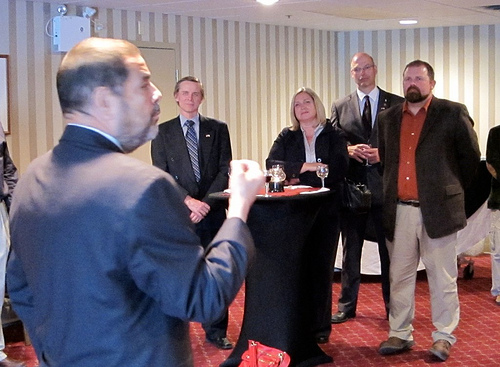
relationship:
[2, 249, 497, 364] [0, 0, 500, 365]
carpet on room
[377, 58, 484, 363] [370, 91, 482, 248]
guy in brown blazer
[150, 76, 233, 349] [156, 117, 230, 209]
man in suit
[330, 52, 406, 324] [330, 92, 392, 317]
man in suit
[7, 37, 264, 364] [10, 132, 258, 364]
man in suit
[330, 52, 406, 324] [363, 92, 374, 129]
man wearing tie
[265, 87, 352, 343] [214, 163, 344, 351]
person behind table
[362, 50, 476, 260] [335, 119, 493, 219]
man wearing shirt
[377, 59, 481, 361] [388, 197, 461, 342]
guy wearing pants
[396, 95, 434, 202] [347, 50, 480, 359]
shirt on man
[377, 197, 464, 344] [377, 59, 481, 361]
pants on guy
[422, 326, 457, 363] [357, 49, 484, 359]
shoe on man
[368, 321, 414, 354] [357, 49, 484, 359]
shoe on man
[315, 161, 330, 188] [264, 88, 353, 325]
glass near woman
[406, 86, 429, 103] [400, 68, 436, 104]
beard on man's face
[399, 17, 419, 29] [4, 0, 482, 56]
light in ceiling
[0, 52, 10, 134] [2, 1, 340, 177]
picture on wall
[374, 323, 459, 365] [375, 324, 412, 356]
loafers on foot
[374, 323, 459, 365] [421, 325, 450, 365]
loafers on foot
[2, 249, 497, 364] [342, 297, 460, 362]
carpet on floor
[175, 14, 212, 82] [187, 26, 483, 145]
stripe on wall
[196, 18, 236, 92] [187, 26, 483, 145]
stripe on wall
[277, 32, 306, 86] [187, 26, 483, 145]
stripe on wall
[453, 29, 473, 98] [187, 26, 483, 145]
stripe on wall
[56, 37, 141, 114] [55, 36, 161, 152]
hair on head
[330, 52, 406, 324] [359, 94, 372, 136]
man wearing a tie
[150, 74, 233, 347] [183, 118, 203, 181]
man wearing a tie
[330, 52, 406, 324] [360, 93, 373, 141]
man wearing a tie